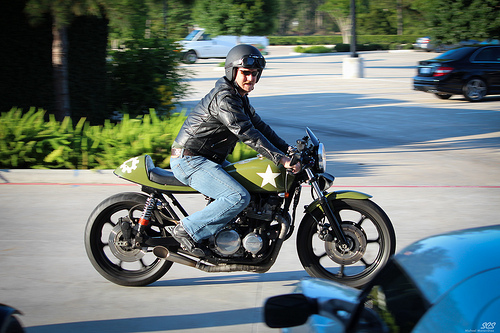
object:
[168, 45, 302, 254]
man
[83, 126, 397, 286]
motorcycle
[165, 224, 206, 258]
shoe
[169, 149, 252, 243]
jeans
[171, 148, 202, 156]
belt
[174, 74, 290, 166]
jacket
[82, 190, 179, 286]
wheel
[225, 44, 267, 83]
helmet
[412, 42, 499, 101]
car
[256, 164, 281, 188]
logo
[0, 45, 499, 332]
parking lot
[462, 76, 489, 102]
tire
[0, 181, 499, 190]
line